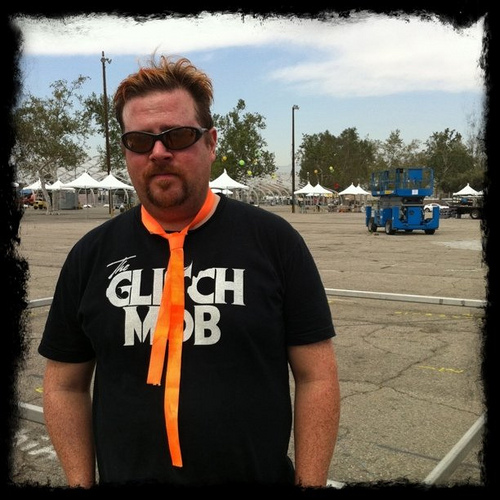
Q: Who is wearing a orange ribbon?
A: The man.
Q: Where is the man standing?
A: On pavement.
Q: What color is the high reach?
A: Blue.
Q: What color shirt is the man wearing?
A: Black.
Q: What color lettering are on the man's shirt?
A: White.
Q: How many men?
A: One man.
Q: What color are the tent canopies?
A: White.